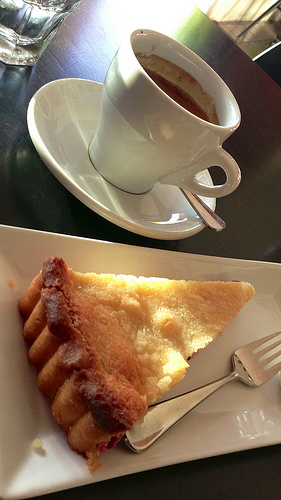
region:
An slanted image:
[7, 6, 277, 495]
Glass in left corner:
[1, 0, 85, 75]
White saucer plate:
[24, 75, 115, 180]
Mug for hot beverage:
[88, 26, 238, 160]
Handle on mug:
[158, 152, 241, 194]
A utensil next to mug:
[170, 189, 229, 231]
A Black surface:
[243, 69, 277, 258]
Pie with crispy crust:
[17, 254, 223, 368]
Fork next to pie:
[220, 330, 280, 399]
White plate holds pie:
[5, 436, 60, 490]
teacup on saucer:
[27, 27, 242, 238]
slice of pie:
[13, 254, 253, 458]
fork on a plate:
[125, 329, 280, 455]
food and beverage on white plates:
[3, 17, 276, 482]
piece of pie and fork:
[21, 255, 279, 457]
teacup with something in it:
[68, 30, 241, 197]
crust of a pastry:
[10, 257, 125, 456]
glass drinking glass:
[1, 0, 88, 65]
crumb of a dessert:
[29, 435, 47, 450]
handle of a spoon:
[184, 197, 226, 231]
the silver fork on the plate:
[126, 322, 280, 456]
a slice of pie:
[22, 255, 258, 454]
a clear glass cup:
[0, 0, 80, 66]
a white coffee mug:
[91, 25, 243, 194]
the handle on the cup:
[161, 146, 243, 196]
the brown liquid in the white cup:
[142, 61, 210, 116]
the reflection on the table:
[102, 2, 197, 34]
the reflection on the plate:
[228, 408, 276, 438]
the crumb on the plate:
[25, 436, 46, 448]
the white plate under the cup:
[29, 74, 219, 238]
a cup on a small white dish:
[28, 18, 247, 245]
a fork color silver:
[118, 318, 280, 463]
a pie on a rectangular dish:
[0, 221, 280, 497]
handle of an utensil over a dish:
[179, 185, 230, 236]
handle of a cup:
[162, 140, 244, 199]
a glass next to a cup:
[2, 2, 82, 75]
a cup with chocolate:
[79, 18, 252, 200]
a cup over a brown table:
[1, 1, 279, 257]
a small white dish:
[22, 72, 226, 243]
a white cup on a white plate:
[27, 13, 240, 240]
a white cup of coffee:
[92, 25, 240, 208]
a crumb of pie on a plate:
[30, 437, 45, 450]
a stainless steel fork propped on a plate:
[123, 323, 279, 457]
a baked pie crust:
[18, 253, 131, 452]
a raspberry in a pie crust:
[95, 432, 123, 454]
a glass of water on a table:
[0, 0, 81, 65]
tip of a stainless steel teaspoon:
[180, 188, 227, 231]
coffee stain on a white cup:
[161, 67, 185, 79]